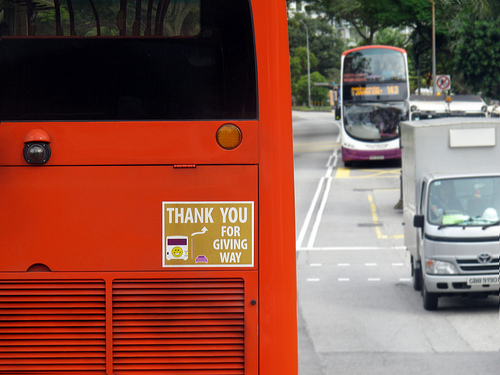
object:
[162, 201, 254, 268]
sign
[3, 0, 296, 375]
bus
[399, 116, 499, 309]
truck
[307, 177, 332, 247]
lines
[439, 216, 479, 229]
wipers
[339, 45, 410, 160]
front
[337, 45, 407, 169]
bus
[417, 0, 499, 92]
trees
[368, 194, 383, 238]
lines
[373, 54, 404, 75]
light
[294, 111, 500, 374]
road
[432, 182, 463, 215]
person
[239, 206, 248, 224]
white letters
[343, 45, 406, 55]
roof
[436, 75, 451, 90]
sign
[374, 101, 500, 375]
right side of street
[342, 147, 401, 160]
bumper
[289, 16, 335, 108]
tree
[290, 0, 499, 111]
distance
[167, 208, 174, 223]
t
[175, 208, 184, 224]
h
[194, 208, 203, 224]
n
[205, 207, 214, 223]
k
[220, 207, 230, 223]
y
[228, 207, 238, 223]
o